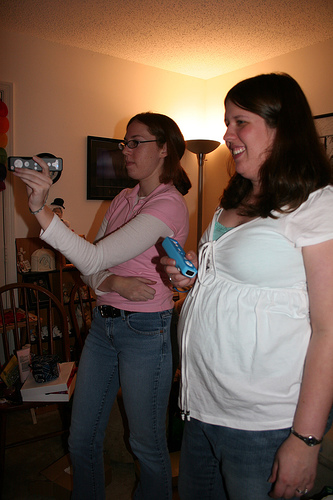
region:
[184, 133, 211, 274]
a long floor lamp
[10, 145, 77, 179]
a black video game controller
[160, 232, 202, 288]
a blue video game controller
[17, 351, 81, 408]
a white cardboard box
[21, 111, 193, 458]
a young girl in a pink shirt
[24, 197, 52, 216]
bracelet on the girl in pink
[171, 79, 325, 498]
a young woman in a white shirt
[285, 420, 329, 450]
a watch on the woman in white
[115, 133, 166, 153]
glasses on the woman in pink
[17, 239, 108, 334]
wooden shelves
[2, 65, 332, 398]
two people playing video games.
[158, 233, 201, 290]
person holding blue wii remote.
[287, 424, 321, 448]
woman wearing a bracelet.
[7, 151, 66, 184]
the remote is black.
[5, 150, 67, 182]
person holding a remote.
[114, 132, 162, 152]
glasses on woman's face.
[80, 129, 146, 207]
the tv is black.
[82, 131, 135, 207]
the tv is off.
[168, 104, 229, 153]
the light is on.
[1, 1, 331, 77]
the ceiling is white.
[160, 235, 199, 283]
baby blue game controller in womans hand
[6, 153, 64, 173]
gray game controller in competitors hand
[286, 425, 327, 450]
silver watch on wrist of woman playing video game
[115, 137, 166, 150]
glasses on face of woman playing video game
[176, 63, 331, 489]
pregant woman playing video game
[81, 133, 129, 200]
picture hanging on wall in living room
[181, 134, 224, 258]
floor lamp in the corner of the room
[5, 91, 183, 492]
woman playing video game with friend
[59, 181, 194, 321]
the woman is wearing a pink and white top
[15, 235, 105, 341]
a curio cabinet next to the door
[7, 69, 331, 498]
two women playing a video game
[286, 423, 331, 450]
watch on woman's wrist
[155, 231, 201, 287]
blue Wii remote in woman's hand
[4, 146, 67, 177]
grey Wii remote in woman's hand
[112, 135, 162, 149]
glasses on a woman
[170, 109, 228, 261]
illuminated light in a corner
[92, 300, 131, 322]
black belt on a woman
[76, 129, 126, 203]
picture on a wall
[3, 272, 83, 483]
wooden chair on a floor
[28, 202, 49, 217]
bracelet on woman's wrist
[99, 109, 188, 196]
a woman wearing glasses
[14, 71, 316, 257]
two woman holding game controllers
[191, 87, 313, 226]
a woman with brown hair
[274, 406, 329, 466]
a woman wearing a watch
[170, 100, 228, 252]
a tall lamp in the corner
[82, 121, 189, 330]
a woman wearing a black belt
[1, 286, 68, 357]
a wooden chair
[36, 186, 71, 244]
a doll sitting on a shelf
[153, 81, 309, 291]
a woman holding a blue controller